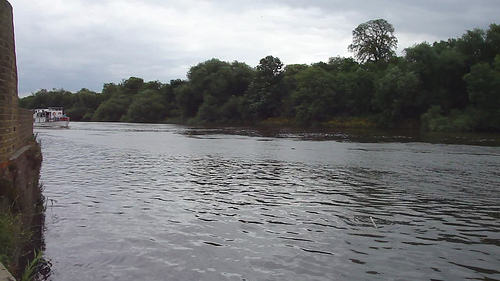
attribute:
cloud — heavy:
[285, 0, 495, 37]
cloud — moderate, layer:
[45, 43, 118, 73]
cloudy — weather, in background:
[10, 2, 495, 98]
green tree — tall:
[347, 17, 397, 69]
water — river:
[29, 117, 498, 279]